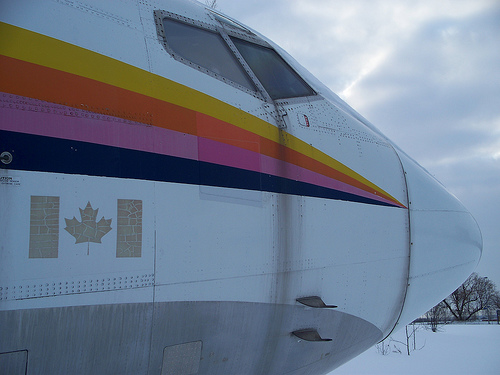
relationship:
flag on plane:
[22, 190, 145, 265] [2, 1, 487, 375]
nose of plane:
[400, 150, 486, 333] [2, 1, 487, 375]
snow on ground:
[318, 310, 499, 374] [325, 317, 499, 374]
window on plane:
[223, 30, 322, 118] [2, 1, 487, 375]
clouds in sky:
[273, 2, 472, 109] [199, 2, 499, 312]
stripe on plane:
[0, 21, 412, 209] [2, 1, 487, 375]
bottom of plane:
[2, 297, 390, 375] [2, 1, 487, 375]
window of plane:
[223, 30, 322, 118] [2, 1, 487, 375]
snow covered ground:
[318, 310, 499, 374] [325, 317, 499, 374]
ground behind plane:
[325, 317, 499, 374] [2, 1, 487, 375]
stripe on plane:
[2, 55, 400, 203] [2, 1, 487, 375]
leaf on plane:
[62, 199, 115, 261] [2, 1, 487, 375]